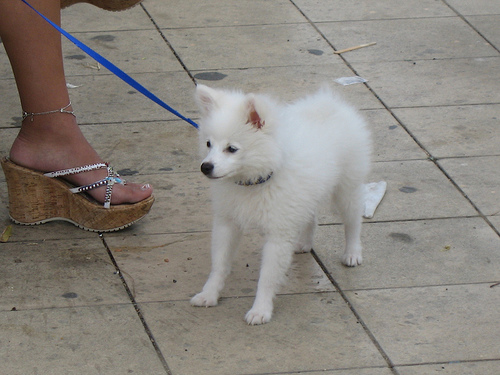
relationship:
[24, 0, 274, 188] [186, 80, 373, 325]
blue leash on dog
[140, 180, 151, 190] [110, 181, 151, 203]
toenail on toe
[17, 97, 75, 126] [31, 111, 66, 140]
ankle bracelet on ankle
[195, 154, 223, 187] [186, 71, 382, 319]
nose on dog